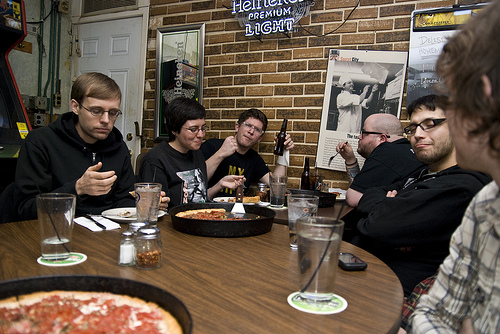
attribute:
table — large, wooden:
[1, 211, 405, 333]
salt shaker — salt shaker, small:
[116, 230, 134, 266]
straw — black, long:
[300, 201, 345, 296]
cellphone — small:
[339, 252, 368, 270]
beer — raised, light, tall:
[276, 117, 289, 154]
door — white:
[75, 15, 136, 172]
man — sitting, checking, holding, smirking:
[12, 71, 171, 218]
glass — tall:
[297, 215, 345, 303]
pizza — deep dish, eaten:
[0, 290, 181, 333]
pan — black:
[0, 275, 194, 334]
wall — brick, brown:
[140, 1, 499, 198]